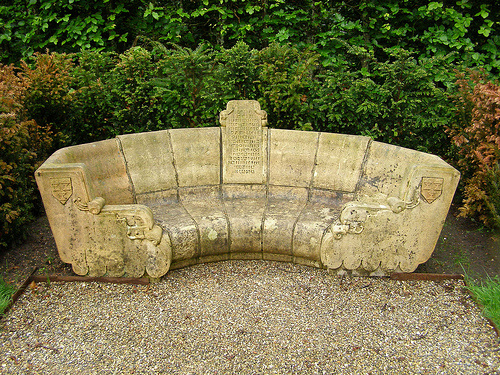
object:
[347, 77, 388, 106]
leaves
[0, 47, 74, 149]
tree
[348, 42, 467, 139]
tree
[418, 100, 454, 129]
leaves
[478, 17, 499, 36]
leaves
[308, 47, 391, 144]
tree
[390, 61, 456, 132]
tree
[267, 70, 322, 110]
leaves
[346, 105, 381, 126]
leaves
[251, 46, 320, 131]
tree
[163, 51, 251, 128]
tree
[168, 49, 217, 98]
leaves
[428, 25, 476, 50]
leaves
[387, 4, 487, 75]
tree